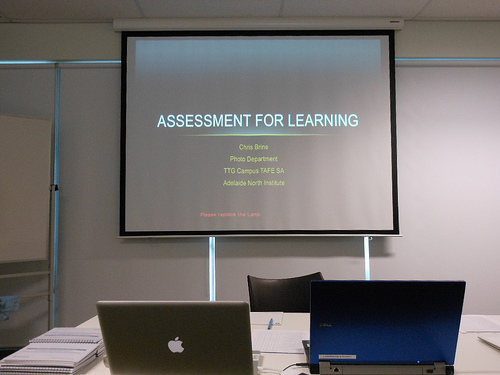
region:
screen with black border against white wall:
[12, 16, 493, 307]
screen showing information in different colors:
[117, 37, 397, 234]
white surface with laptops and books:
[11, 300, 496, 365]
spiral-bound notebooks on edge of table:
[0, 311, 100, 371]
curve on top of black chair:
[240, 266, 332, 316]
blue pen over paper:
[250, 307, 300, 342]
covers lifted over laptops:
[90, 272, 477, 367]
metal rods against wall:
[1, 50, 487, 306]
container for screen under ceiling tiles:
[101, 5, 406, 35]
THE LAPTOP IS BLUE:
[295, 265, 485, 372]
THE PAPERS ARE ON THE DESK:
[233, 307, 318, 358]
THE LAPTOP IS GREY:
[83, 283, 255, 373]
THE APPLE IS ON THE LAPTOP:
[155, 330, 191, 360]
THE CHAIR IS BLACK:
[245, 270, 345, 317]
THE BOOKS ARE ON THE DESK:
[0, 310, 108, 372]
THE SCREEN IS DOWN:
[103, 15, 414, 242]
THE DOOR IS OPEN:
[0, 60, 65, 345]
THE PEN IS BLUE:
[262, 315, 275, 335]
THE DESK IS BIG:
[5, 298, 499, 374]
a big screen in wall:
[132, 53, 419, 244]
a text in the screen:
[138, 90, 385, 167]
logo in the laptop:
[163, 336, 200, 361]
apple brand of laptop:
[155, 335, 203, 373]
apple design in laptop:
[148, 329, 195, 361]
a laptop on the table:
[95, 293, 251, 374]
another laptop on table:
[291, 266, 451, 370]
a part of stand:
[354, 238, 383, 283]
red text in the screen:
[169, 181, 282, 226]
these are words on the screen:
[152, 113, 363, 128]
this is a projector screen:
[117, 30, 398, 241]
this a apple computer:
[95, 302, 256, 374]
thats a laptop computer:
[298, 278, 467, 374]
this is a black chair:
[245, 268, 327, 310]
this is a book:
[2, 324, 117, 371]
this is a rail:
[1, 57, 497, 67]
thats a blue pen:
[267, 315, 274, 327]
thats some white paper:
[250, 306, 285, 326]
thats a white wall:
[0, 0, 498, 348]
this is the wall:
[430, 110, 474, 200]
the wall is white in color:
[416, 117, 434, 144]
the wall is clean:
[440, 122, 470, 178]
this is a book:
[3, 321, 107, 371]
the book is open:
[2, 320, 89, 370]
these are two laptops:
[91, 283, 466, 373]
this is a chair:
[250, 280, 299, 312]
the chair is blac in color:
[267, 278, 288, 300]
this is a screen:
[127, 35, 399, 228]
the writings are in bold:
[158, 110, 355, 135]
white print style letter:
[156, 113, 167, 130]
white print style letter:
[163, 109, 177, 128]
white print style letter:
[175, 115, 187, 130]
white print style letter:
[184, 112, 196, 132]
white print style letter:
[194, 114, 206, 127]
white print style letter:
[210, 108, 227, 131]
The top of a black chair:
[237, 256, 332, 316]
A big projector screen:
[110, 21, 407, 246]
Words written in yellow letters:
[215, 135, 295, 195]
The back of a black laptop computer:
[296, 266, 473, 371]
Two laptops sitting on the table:
[0, 270, 495, 370]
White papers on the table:
[240, 300, 312, 358]